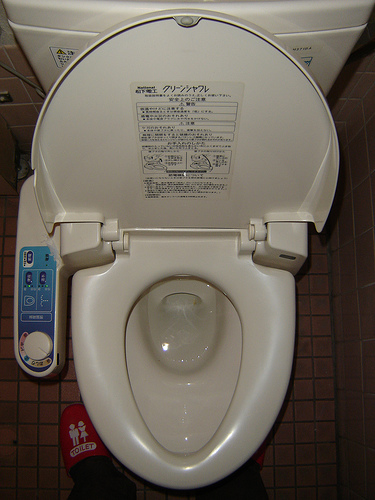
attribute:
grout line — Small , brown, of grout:
[0, 399, 82, 402]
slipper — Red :
[56, 401, 114, 474]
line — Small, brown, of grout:
[304, 280, 322, 428]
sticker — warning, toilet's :
[53, 49, 76, 70]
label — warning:
[48, 46, 81, 72]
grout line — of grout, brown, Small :
[307, 299, 315, 324]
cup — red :
[55, 398, 112, 488]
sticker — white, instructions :
[132, 80, 245, 198]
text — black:
[135, 83, 230, 200]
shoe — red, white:
[51, 400, 123, 498]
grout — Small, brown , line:
[314, 395, 335, 400]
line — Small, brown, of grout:
[321, 255, 369, 496]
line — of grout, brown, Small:
[0, 441, 59, 449]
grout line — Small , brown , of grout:
[325, 229, 343, 498]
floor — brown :
[3, 380, 86, 498]